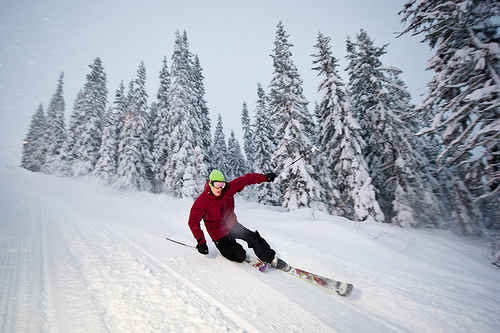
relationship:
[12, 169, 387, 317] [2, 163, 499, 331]
ski slope covered in snow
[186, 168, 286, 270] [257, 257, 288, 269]
man skiing down shoes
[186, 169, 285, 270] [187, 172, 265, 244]
man wearing jacket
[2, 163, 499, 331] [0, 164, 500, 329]
snow on hillside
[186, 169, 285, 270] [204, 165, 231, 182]
man wearing hat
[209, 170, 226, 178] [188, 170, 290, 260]
hat on man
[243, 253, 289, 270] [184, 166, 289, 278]
shoes on man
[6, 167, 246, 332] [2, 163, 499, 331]
tracks in snow